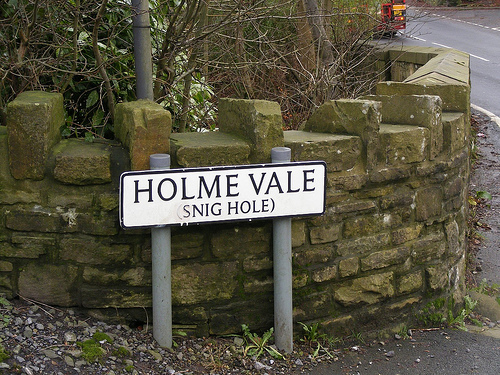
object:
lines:
[408, 7, 499, 81]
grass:
[415, 280, 485, 333]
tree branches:
[152, 0, 442, 132]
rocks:
[8, 91, 65, 181]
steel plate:
[120, 160, 330, 231]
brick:
[394, 288, 468, 331]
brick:
[0, 232, 51, 258]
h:
[132, 178, 154, 203]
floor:
[300, 325, 498, 373]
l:
[180, 177, 194, 201]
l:
[285, 171, 299, 193]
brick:
[17, 260, 82, 308]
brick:
[335, 269, 399, 312]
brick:
[364, 243, 410, 270]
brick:
[309, 220, 344, 244]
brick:
[410, 227, 451, 264]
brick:
[374, 185, 416, 208]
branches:
[0, 1, 461, 131]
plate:
[117, 150, 329, 230]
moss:
[81, 334, 129, 360]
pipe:
[131, 0, 158, 104]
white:
[118, 159, 328, 230]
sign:
[117, 157, 327, 231]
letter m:
[198, 175, 221, 200]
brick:
[305, 97, 385, 134]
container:
[0, 35, 472, 330]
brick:
[415, 191, 445, 221]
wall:
[0, 38, 472, 348]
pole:
[268, 146, 294, 355]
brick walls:
[0, 46, 472, 349]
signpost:
[115, 147, 329, 355]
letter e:
[225, 174, 239, 198]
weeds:
[219, 324, 283, 364]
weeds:
[295, 321, 334, 358]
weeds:
[442, 311, 466, 329]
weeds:
[0, 294, 10, 361]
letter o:
[156, 178, 178, 201]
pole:
[145, 151, 173, 348]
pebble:
[0, 298, 147, 375]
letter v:
[247, 172, 266, 195]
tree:
[0, 0, 304, 143]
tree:
[236, 0, 438, 142]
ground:
[0, 7, 499, 374]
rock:
[0, 280, 500, 375]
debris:
[0, 305, 477, 374]